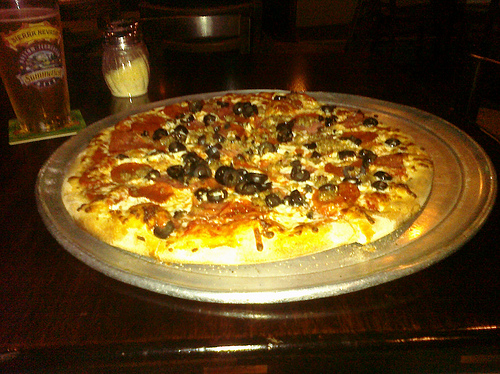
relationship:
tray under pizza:
[41, 79, 479, 308] [81, 87, 387, 272]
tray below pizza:
[41, 79, 479, 308] [81, 87, 387, 272]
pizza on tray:
[81, 87, 387, 272] [41, 79, 479, 308]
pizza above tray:
[81, 87, 387, 272] [41, 79, 479, 308]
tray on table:
[41, 79, 479, 308] [9, 40, 496, 369]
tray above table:
[41, 79, 479, 308] [9, 40, 496, 369]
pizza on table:
[81, 87, 387, 272] [9, 40, 496, 369]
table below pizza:
[9, 40, 496, 369] [81, 87, 387, 272]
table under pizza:
[9, 40, 496, 369] [81, 87, 387, 272]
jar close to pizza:
[92, 12, 169, 112] [81, 87, 387, 272]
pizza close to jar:
[81, 87, 387, 272] [92, 12, 169, 112]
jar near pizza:
[92, 12, 169, 112] [81, 87, 387, 272]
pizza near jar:
[81, 87, 387, 272] [92, 12, 169, 112]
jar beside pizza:
[92, 12, 169, 112] [81, 87, 387, 272]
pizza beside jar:
[81, 87, 387, 272] [92, 12, 169, 112]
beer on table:
[1, 1, 95, 137] [9, 40, 496, 369]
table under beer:
[9, 40, 496, 369] [1, 1, 95, 137]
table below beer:
[9, 40, 496, 369] [1, 1, 95, 137]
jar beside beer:
[92, 12, 169, 112] [1, 1, 95, 137]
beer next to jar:
[1, 1, 95, 137] [92, 12, 169, 112]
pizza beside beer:
[81, 87, 387, 272] [1, 1, 95, 137]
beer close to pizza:
[1, 1, 95, 137] [81, 87, 387, 272]